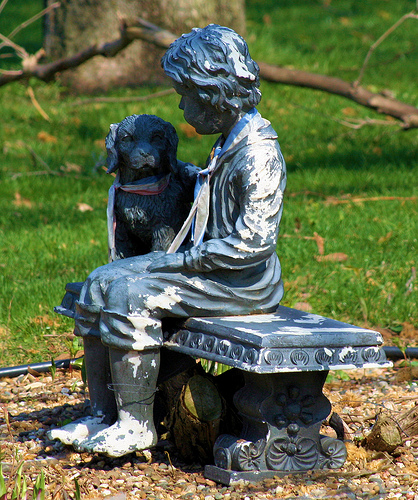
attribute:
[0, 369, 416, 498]
rocks — brown, white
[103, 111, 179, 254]
dog — stone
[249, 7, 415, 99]
area — large, grassy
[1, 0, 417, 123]
branch — brown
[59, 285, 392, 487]
bench — decorated, gray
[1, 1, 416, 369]
grass — green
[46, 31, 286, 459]
boy — stone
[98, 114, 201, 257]
dog — gray, stone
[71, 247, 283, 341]
pants — rolled up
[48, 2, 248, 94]
tree — large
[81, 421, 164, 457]
paint — chipping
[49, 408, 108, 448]
paint — chipping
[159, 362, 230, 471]
trunk — brown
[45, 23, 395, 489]
statue — grey, stone